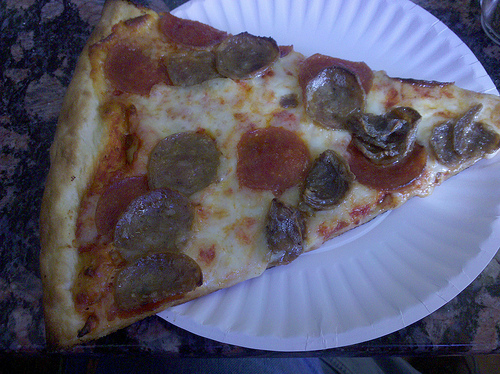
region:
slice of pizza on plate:
[39, 19, 460, 295]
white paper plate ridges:
[361, 20, 451, 65]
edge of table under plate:
[404, 321, 487, 362]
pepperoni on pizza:
[239, 111, 314, 191]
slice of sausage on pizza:
[138, 100, 228, 205]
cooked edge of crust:
[35, 69, 97, 196]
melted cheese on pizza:
[186, 84, 253, 134]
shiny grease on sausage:
[306, 79, 342, 116]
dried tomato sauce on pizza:
[95, 130, 136, 184]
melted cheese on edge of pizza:
[207, 254, 284, 301]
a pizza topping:
[121, 249, 195, 304]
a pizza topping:
[113, 187, 194, 259]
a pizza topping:
[151, 130, 216, 197]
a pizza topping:
[96, 177, 160, 249]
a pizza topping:
[238, 125, 308, 194]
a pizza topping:
[315, 156, 351, 214]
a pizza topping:
[303, 55, 361, 143]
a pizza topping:
[427, 105, 476, 160]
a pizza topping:
[209, 35, 276, 79]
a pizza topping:
[108, 34, 173, 101]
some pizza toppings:
[96, 244, 205, 301]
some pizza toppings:
[110, 177, 188, 259]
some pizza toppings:
[273, 200, 306, 265]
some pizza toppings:
[299, 145, 354, 212]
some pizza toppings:
[233, 120, 312, 192]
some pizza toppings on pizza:
[143, 130, 213, 190]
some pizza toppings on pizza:
[91, 170, 162, 241]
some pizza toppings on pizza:
[345, 108, 406, 155]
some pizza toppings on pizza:
[350, 136, 430, 196]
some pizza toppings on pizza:
[435, 108, 480, 159]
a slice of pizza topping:
[115, 253, 199, 310]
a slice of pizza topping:
[116, 185, 188, 255]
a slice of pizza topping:
[268, 206, 311, 253]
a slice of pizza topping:
[303, 143, 353, 215]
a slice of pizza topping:
[241, 120, 305, 200]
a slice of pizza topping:
[148, 130, 216, 201]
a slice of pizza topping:
[305, 55, 362, 139]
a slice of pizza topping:
[212, 27, 282, 85]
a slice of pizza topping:
[109, 44, 163, 104]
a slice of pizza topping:
[348, 130, 421, 192]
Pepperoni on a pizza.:
[218, 117, 315, 192]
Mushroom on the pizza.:
[291, 145, 368, 216]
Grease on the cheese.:
[215, 73, 265, 114]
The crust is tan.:
[38, 144, 94, 234]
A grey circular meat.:
[147, 128, 231, 206]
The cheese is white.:
[180, 93, 237, 134]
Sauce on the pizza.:
[89, 143, 161, 180]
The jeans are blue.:
[232, 359, 332, 373]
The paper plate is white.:
[360, 230, 445, 299]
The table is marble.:
[0, 8, 86, 53]